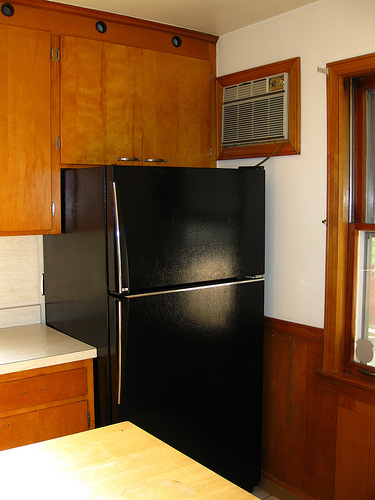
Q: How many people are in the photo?
A: None.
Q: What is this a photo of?
A: A kitchen.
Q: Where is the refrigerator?
A: Under the cupboard.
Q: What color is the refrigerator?
A: Black.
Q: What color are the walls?
A: White.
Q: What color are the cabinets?
A: Brown.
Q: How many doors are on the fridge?
A: Two.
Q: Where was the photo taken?
A: In a kitchen.